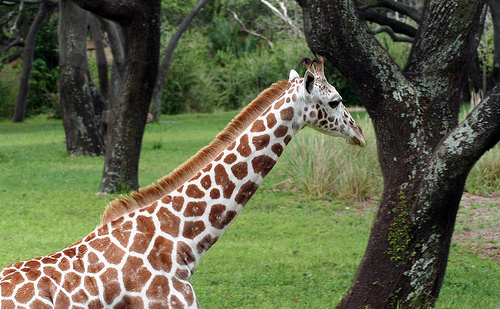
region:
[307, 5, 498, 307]
tree with moss next to giraffe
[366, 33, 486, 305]
green moss on the tree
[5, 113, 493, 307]
green grass behind the giraffe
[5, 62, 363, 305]
a spotted giraffe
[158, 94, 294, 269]
the giraffe's long neck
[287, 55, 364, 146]
the giraffe's head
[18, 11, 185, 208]
several trees behind the giraffe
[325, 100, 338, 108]
the giraffe's right eye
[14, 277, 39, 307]
The spot is brown.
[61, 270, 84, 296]
The spot is brown.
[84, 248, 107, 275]
The spot is brown.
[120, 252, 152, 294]
The spot is brown.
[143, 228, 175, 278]
The spot is brown.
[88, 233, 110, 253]
The spot is brown.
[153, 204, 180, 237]
The spot is brown.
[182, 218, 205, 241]
The spot is brown.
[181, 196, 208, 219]
The spot is brown.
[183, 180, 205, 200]
The spot is brown.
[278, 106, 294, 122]
brown spot on giraffe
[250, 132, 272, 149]
brown spot on giraffe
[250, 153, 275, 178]
brown spot on giraffe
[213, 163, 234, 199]
brown spot on giraffe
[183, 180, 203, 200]
brown spot on giraffe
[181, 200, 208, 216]
brown spot on giraffe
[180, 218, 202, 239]
brown spot on giraffe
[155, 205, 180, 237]
brown spot on giraffe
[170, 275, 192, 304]
brown spot on giraffe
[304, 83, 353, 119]
the head of a giraffe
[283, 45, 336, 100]
the ear of a giraffe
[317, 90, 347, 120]
the eye of a giraffe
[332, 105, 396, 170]
the mouth of a giraffe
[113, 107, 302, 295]
the neck of a giraffe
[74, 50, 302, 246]
the main of a giraffe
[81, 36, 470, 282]
a giraffe near a tree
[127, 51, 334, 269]
a brown spotted giraffe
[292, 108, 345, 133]
the jaw of a giraffe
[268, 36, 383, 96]
the horns of a giraffe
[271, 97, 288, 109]
brown spot on giraffe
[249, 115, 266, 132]
brown spot on giraffe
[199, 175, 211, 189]
brown spot on giraffe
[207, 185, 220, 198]
brown spot on giraffe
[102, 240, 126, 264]
brown spot on giraffe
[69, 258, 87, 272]
brown spot on giraffe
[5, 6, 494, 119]
The forest of trees in the background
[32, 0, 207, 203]
The tree trunks behind the giraffe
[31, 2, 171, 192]
A set of tree trunks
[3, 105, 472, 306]
The green lawn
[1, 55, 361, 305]
the giraffe in front of the tree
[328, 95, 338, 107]
the eye on the giraffe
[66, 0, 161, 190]
the tree behind the giraffe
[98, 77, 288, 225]
the mane on the giraffe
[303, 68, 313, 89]
the right ear on the giraffe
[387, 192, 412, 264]
the moss on the tree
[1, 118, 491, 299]
the grass on the ground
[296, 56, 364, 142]
the head of the giraffe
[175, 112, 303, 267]
the neck on the giraffe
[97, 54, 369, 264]
red mane on back of giraffe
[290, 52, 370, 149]
horns on giraffe head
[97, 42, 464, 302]
giraffe standing by tree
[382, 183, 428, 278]
green moss on tree trunk